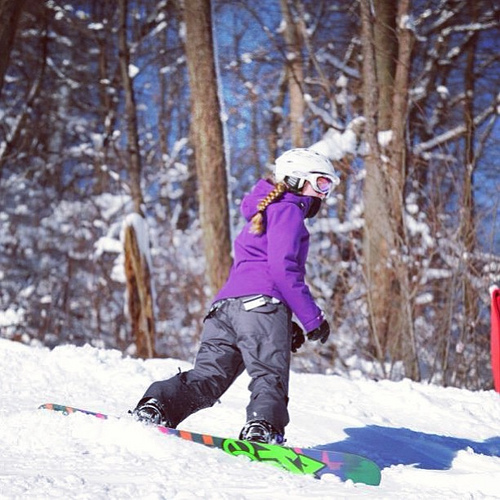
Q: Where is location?
A: A ski resort.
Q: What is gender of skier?
A: A male.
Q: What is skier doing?
A: Snow boarding.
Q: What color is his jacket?
A: Blue.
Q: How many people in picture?
A: One.